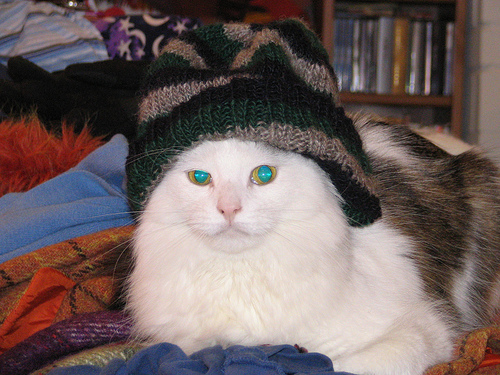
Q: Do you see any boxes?
A: No, there are no boxes.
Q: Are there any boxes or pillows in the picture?
A: No, there are no boxes or pillows.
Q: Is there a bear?
A: No, there are no bears.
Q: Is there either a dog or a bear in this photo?
A: No, there are no bears or dogs.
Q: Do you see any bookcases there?
A: Yes, there is a bookcase.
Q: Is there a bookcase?
A: Yes, there is a bookcase.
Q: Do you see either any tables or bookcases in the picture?
A: Yes, there is a bookcase.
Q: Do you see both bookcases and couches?
A: No, there is a bookcase but no couches.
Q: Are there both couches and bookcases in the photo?
A: No, there is a bookcase but no couches.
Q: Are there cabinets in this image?
A: No, there are no cabinets.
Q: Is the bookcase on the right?
A: Yes, the bookcase is on the right of the image.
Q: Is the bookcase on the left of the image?
A: No, the bookcase is on the right of the image.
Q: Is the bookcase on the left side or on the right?
A: The bookcase is on the right of the image.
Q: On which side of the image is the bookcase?
A: The bookcase is on the right of the image.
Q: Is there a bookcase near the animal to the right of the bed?
A: Yes, there is a bookcase near the cat.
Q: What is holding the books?
A: The bookcase is holding the books.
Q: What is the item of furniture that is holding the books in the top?
A: The piece of furniture is a bookcase.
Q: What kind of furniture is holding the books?
A: The piece of furniture is a bookcase.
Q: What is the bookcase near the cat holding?
A: The bookcase is holding the books.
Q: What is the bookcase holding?
A: The bookcase is holding the books.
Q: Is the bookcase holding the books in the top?
A: Yes, the bookcase is holding the books.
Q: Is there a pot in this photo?
A: No, there are no pots.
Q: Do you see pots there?
A: No, there are no pots.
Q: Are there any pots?
A: No, there are no pots.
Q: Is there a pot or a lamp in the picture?
A: No, there are no pots or lamps.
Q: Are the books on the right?
A: Yes, the books are on the right of the image.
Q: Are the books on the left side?
A: No, the books are on the right of the image.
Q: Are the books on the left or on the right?
A: The books are on the right of the image.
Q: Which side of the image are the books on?
A: The books are on the right of the image.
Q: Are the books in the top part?
A: Yes, the books are in the top of the image.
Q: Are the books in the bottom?
A: No, the books are in the top of the image.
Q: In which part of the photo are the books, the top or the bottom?
A: The books are in the top of the image.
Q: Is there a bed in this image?
A: Yes, there is a bed.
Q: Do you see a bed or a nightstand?
A: Yes, there is a bed.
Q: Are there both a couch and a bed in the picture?
A: No, there is a bed but no couches.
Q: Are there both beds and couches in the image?
A: No, there is a bed but no couches.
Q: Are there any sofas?
A: No, there are no sofas.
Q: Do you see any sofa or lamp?
A: No, there are no sofas or lamps.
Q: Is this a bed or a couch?
A: This is a bed.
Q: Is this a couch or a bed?
A: This is a bed.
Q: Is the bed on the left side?
A: Yes, the bed is on the left of the image.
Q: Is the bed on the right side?
A: No, the bed is on the left of the image.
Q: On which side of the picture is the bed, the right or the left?
A: The bed is on the left of the image.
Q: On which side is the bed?
A: The bed is on the left of the image.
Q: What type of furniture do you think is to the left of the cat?
A: The piece of furniture is a bed.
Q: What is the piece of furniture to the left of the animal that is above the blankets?
A: The piece of furniture is a bed.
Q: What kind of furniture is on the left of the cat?
A: The piece of furniture is a bed.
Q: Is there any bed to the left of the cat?
A: Yes, there is a bed to the left of the cat.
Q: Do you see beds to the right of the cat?
A: No, the bed is to the left of the cat.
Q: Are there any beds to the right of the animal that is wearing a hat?
A: No, the bed is to the left of the cat.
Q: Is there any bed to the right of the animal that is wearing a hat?
A: No, the bed is to the left of the cat.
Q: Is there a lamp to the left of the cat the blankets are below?
A: No, there is a bed to the left of the cat.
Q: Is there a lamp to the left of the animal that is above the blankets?
A: No, there is a bed to the left of the cat.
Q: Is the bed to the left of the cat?
A: Yes, the bed is to the left of the cat.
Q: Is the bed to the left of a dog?
A: No, the bed is to the left of the cat.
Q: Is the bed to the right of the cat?
A: No, the bed is to the left of the cat.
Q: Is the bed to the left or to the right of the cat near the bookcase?
A: The bed is to the left of the cat.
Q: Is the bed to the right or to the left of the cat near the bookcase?
A: The bed is to the left of the cat.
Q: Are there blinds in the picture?
A: No, there are no blinds.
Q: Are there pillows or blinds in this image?
A: No, there are no blinds or pillows.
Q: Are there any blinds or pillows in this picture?
A: No, there are no blinds or pillows.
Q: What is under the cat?
A: The blankets are under the cat.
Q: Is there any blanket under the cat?
A: Yes, there are blankets under the cat.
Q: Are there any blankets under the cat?
A: Yes, there are blankets under the cat.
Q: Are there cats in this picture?
A: Yes, there is a cat.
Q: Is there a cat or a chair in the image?
A: Yes, there is a cat.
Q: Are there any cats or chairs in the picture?
A: Yes, there is a cat.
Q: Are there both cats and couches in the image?
A: No, there is a cat but no couches.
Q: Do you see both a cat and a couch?
A: No, there is a cat but no couches.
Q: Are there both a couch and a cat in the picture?
A: No, there is a cat but no couches.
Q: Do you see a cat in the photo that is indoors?
A: Yes, there is a cat that is indoors.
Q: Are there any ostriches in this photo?
A: No, there are no ostriches.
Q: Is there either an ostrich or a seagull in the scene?
A: No, there are no ostriches or seagulls.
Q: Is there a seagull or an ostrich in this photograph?
A: No, there are no ostriches or seagulls.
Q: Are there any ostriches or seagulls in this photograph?
A: No, there are no ostriches or seagulls.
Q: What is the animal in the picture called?
A: The animal is a cat.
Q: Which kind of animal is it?
A: The animal is a cat.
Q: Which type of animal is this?
A: That is a cat.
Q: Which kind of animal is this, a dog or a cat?
A: That is a cat.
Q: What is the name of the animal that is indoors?
A: The animal is a cat.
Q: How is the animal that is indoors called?
A: The animal is a cat.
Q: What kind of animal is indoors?
A: The animal is a cat.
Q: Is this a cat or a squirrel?
A: This is a cat.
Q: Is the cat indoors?
A: Yes, the cat is indoors.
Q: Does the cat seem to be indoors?
A: Yes, the cat is indoors.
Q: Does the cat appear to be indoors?
A: Yes, the cat is indoors.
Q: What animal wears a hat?
A: The cat wears a hat.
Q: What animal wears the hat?
A: The cat wears a hat.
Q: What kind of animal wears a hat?
A: The animal is a cat.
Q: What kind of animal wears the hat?
A: The animal is a cat.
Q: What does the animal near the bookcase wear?
A: The cat wears a hat.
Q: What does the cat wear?
A: The cat wears a hat.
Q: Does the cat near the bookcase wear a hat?
A: Yes, the cat wears a hat.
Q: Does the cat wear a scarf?
A: No, the cat wears a hat.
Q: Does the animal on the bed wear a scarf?
A: No, the cat wears a hat.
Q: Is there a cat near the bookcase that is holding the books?
A: Yes, there is a cat near the bookcase.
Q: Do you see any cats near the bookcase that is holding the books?
A: Yes, there is a cat near the bookcase.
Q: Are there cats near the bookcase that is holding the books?
A: Yes, there is a cat near the bookcase.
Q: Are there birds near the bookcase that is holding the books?
A: No, there is a cat near the bookcase.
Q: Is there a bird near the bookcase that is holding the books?
A: No, there is a cat near the bookcase.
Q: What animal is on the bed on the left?
A: The cat is on the bed.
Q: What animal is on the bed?
A: The cat is on the bed.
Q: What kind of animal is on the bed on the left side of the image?
A: The animal is a cat.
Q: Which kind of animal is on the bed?
A: The animal is a cat.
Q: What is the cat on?
A: The cat is on the bed.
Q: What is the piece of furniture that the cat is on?
A: The piece of furniture is a bed.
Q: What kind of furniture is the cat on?
A: The cat is on the bed.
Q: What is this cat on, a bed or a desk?
A: The cat is on a bed.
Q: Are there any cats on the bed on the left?
A: Yes, there is a cat on the bed.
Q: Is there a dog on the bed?
A: No, there is a cat on the bed.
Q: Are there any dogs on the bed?
A: No, there is a cat on the bed.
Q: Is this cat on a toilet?
A: No, the cat is on a bed.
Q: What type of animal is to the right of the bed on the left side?
A: The animal is a cat.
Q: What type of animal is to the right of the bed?
A: The animal is a cat.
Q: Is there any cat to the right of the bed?
A: Yes, there is a cat to the right of the bed.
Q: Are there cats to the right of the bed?
A: Yes, there is a cat to the right of the bed.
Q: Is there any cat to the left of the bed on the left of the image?
A: No, the cat is to the right of the bed.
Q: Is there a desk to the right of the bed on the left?
A: No, there is a cat to the right of the bed.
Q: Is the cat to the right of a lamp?
A: No, the cat is to the right of the bed.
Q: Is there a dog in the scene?
A: No, there are no dogs.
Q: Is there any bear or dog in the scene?
A: No, there are no dogs or bears.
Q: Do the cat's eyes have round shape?
A: Yes, the eyes are round.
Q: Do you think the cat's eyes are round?
A: Yes, the eyes are round.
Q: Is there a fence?
A: No, there are no fences.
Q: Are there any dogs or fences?
A: No, there are no fences or dogs.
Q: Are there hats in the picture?
A: Yes, there is a hat.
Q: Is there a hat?
A: Yes, there is a hat.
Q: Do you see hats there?
A: Yes, there is a hat.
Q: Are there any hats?
A: Yes, there is a hat.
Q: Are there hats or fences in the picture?
A: Yes, there is a hat.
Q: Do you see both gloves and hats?
A: No, there is a hat but no gloves.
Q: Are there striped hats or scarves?
A: Yes, there is a striped hat.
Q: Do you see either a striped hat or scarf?
A: Yes, there is a striped hat.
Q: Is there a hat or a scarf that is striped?
A: Yes, the hat is striped.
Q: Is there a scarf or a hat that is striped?
A: Yes, the hat is striped.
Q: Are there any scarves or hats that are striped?
A: Yes, the hat is striped.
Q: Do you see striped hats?
A: Yes, there is a striped hat.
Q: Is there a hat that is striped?
A: Yes, there is a hat that is striped.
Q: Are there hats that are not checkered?
A: Yes, there is a striped hat.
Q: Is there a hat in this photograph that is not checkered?
A: Yes, there is a striped hat.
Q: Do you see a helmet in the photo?
A: No, there are no helmets.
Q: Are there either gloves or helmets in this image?
A: No, there are no helmets or gloves.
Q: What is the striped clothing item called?
A: The clothing item is a hat.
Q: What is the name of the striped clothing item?
A: The clothing item is a hat.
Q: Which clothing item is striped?
A: The clothing item is a hat.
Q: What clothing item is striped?
A: The clothing item is a hat.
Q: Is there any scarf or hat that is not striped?
A: No, there is a hat but it is striped.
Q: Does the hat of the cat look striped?
A: Yes, the hat is striped.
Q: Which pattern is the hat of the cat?
A: The hat is striped.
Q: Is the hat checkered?
A: No, the hat is striped.